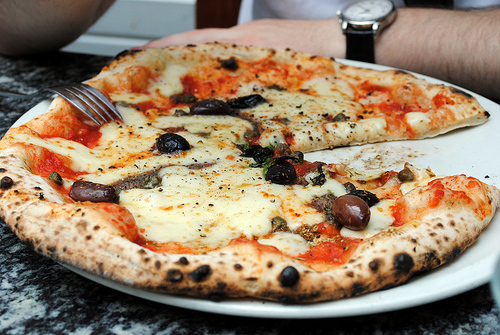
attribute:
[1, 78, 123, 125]
fork — silver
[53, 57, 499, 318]
plate — white, white color, color white, porcelain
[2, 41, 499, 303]
pizza — toasted, spiced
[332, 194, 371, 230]
black olive — whole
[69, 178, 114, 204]
black olive — whole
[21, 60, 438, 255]
cheese — melted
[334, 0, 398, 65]
watch — black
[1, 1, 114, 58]
elbow — hairy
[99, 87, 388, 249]
seasoning — sprinkled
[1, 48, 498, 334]
counter top — marble, dark granite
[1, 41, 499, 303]
crust — brown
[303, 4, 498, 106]
arm — hairy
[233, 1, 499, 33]
shirt — white